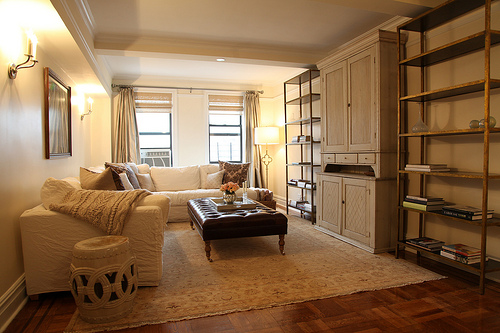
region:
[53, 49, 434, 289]
small beige living room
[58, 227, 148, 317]
basket style table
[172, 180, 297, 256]
brown vinyl padded coffee table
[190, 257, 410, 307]
beige carpet on wood floor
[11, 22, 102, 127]
electric wall sconce lights are on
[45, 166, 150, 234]
beige blanket on off white couch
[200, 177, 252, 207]
bowl of flowers on coffee table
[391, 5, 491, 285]
shelf with some books on bottom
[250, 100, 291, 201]
floor lamp in corner is turned on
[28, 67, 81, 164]
framed art on wall above couch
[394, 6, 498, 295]
the shelf is brown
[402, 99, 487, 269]
books are on the shelf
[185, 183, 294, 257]
the table is brown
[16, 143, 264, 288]
the couch is white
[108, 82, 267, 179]
the curtains are open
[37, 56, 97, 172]
a picture is framed above couch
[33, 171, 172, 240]
a blanket is on couch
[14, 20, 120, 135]
lights on wall are turned on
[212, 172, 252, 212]
flowers are on the table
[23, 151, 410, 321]
the couch is on a carpet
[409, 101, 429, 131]
Glass vase on a shelf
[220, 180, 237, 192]
Pink flowers in a vase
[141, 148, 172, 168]
Air conditioner in a window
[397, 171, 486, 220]
Books stacked on a wooden shelf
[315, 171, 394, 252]
Wooden cabinet with closed doors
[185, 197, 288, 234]
Leather ottoman on a rug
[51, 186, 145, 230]
Tan blanket on a couch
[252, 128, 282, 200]
Lamp in the corner of a room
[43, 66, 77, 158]
Picture on a tan wall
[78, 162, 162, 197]
Pillows stacked on a couch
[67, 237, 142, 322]
tan decorative vase next to sofa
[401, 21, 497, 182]
tall ceiling height wooden bookshelf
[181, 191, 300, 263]
plush brown coffee table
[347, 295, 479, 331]
patterned brown wooden floor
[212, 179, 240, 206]
pink flowers in a vase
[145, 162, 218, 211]
white couch next to window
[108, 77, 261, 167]
window with tan curtains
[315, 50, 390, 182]
closed tan cabinet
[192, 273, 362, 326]
tan rug on wood floor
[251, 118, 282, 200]
tall lamp with decorative stand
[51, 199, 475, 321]
this is the rug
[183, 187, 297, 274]
this is a table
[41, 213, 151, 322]
this is a table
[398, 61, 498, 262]
this is a shelf cade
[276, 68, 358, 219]
this is a book case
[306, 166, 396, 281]
this is a cabinet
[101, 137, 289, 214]
this is a couch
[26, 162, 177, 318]
this is a chair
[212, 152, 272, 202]
this is a pillow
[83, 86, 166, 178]
this is a curtain